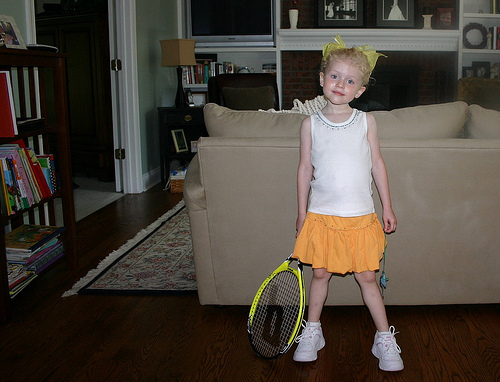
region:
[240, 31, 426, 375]
Girl is holding a tennis racket.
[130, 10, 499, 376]
Girl is standing in livingroom.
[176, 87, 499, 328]
Girl standing behind sofa.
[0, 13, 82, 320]
Wooden bookshelf against wall.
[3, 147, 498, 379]
Livingroom floor is hardwood.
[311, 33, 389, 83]
Girl has yellow bow in hair.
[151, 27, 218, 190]
Lamp on end table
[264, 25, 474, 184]
Sofa faces brick fireplace.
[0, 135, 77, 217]
Books upright on second shelf.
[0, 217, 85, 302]
Books lay flat on bottom shelf.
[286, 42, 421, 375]
a very cute little girl in a tennis outfit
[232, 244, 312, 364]
a child sized tennis racket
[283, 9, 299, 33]
a vase on the mantel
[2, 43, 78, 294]
a bookshelf filled with books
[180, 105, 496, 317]
a big beige couch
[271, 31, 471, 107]
a stone fireplace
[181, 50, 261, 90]
another row of books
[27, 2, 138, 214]
the doorway to another room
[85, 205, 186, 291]
a persian rug on the floor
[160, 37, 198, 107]
a brown lamp in the corner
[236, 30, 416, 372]
young girl holding a tennis racket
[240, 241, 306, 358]
tennis racket has a yellow and black rim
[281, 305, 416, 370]
girl is wearing white shoes and socks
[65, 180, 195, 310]
area rug on the floor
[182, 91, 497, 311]
tan couch behind girl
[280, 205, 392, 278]
girl is wearing a yellow-orange skirt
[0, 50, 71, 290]
books on a dark shelving unit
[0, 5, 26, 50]
a framed photograph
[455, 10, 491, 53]
wreath on shelf in background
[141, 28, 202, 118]
table lamp near wall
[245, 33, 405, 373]
girl holding yellow tennis racket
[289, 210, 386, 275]
little girl wearing yellow skirt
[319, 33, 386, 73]
little girl with yellow bow in hair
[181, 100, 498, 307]
girl in front of beige couch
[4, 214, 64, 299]
books on wood shelf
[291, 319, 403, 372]
girl wearing white shoes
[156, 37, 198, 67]
tan lamp shade is square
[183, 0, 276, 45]
large silver television on shelf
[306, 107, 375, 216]
little girl wearing white tank top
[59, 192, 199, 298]
area rug frayed at end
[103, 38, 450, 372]
The girl is in the living room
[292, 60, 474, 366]
She is wearing a skirt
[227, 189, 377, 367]
She is holding a tennis racket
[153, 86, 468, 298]
The couch is tan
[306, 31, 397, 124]
She is wearing a yellow bow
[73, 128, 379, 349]
There is an area rug in the living room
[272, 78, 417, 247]
She is wearing a white tank top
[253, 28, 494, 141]
There is a fireplace in the living room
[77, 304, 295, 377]
The living room has hardwood floors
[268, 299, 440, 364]
She is wearing white shoes